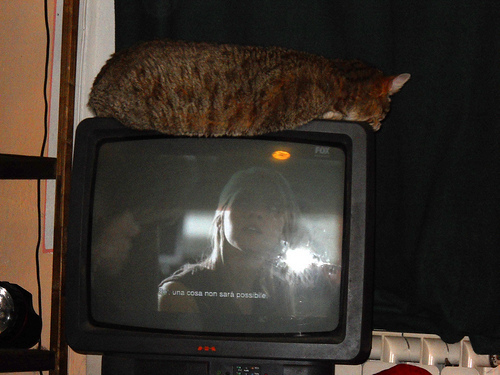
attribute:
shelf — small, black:
[0, 153, 60, 180]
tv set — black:
[55, 107, 382, 373]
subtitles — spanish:
[128, 268, 290, 316]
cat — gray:
[86, 37, 411, 139]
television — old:
[61, 109, 371, 373]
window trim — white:
[53, 0, 117, 120]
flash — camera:
[266, 232, 324, 284]